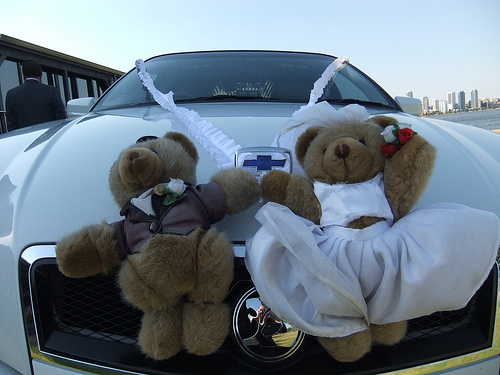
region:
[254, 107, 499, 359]
A stuffed bear in a dress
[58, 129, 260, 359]
A stuffed bear in a tuxedo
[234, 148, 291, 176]
A logo on the car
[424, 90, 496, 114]
The city behind the car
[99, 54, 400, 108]
The windshield of the car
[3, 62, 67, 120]
A man standing next to the car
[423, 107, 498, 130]
A body of water behind the car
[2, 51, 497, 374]
A white car with stuffed bears attached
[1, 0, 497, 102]
The sky above the car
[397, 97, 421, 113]
A mirror on the side of the car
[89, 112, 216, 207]
head of a teddy bear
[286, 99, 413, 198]
of a teddy bear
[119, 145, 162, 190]
mouth of a teddy bear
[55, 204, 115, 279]
arm of a teddy bear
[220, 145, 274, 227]
arm of a teddy bear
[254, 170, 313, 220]
arm of a teddy bear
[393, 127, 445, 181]
arm of a teddy bear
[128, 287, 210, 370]
leg of a teddy bear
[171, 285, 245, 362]
leg of a teddy bear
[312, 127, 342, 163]
an eye of a teddy bear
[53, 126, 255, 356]
Teddy bear on front of car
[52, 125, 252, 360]
Teddy bear is on front of car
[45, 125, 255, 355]
Teddy bear on front of white car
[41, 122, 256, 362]
Teddy bear is on front of white car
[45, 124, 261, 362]
Stuffed animal on front of car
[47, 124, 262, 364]
Stuffed animal is on front of car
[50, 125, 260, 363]
Stuffed animal on front of white car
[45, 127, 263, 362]
Stuffed animal is on front of white car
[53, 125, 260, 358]
Stuffed bear on front of white car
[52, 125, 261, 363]
Stuffed bear is on front of white car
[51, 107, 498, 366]
A couple of bears on a car hood.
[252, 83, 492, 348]
A bear in a white dress.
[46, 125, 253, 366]
a bear in a tuxedo.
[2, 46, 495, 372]
a luxury car with bears on it.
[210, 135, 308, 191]
a chevy logo.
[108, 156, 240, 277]
a bear wearing a suit.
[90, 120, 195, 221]
a bear with a brown head.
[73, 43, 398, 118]
a windshield on a white car.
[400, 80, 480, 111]
a city with tall buildings.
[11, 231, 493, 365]
a grill on a white car.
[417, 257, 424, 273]
part of a cloth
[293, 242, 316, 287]
edge of a cloth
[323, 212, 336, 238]
part of sweater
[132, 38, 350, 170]
white ribbon on vehicle windscreen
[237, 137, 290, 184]
blue cross on front of car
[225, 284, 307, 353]
round silver circle on front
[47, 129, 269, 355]
brown teddy bear in jacket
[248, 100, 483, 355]
brown teddy bear in dress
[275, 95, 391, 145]
white veil on teddy bear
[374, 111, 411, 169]
red and white flowers in bear hand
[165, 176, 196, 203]
white flower on bear jacket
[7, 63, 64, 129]
man in suit jacket